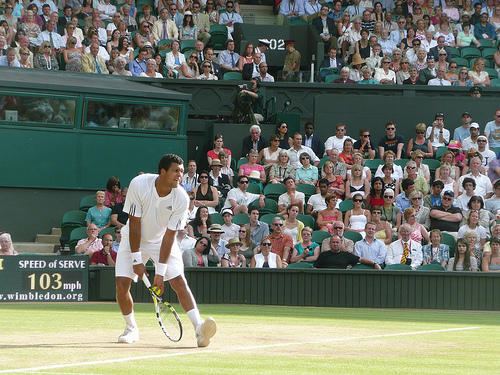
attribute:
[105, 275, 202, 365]
racket — black, tennis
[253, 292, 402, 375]
court — tennis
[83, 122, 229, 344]
man — wearing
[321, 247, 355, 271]
shirt — black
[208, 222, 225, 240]
cap — baseball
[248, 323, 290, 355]
line — white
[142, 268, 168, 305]
ball — tennis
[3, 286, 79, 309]
address — website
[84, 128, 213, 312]
player — tennis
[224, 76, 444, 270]
seating — stadium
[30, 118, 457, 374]
match — tennis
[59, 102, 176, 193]
stadium — green, filled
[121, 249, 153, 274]
wristband — white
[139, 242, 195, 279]
short — sports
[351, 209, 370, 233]
vest — white